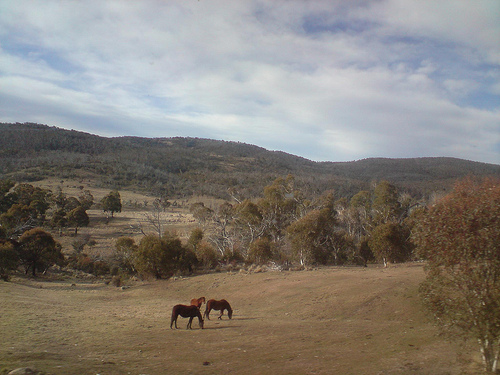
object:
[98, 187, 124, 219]
tree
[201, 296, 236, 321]
horse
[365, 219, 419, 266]
tree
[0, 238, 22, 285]
tree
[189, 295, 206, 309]
horse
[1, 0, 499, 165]
sky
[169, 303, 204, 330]
horses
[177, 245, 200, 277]
tree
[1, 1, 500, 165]
clouds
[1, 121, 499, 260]
mountains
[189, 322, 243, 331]
shadow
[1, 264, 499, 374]
ground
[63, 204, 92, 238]
tree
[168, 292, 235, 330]
three horses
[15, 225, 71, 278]
tree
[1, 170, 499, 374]
field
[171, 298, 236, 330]
two stallions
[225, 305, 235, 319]
horse's head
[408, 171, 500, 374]
tree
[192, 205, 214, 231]
trees